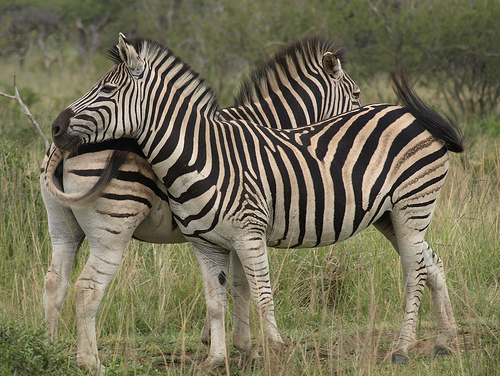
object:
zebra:
[33, 26, 376, 374]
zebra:
[51, 30, 470, 368]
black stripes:
[269, 127, 325, 249]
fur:
[51, 29, 454, 356]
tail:
[386, 67, 466, 154]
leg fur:
[61, 150, 150, 372]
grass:
[0, 0, 499, 376]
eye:
[100, 84, 117, 93]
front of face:
[49, 63, 138, 155]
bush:
[419, 42, 499, 122]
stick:
[0, 70, 52, 150]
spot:
[217, 269, 228, 286]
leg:
[55, 146, 156, 374]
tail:
[43, 144, 133, 210]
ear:
[117, 30, 145, 76]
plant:
[221, 0, 500, 85]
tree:
[1, 0, 126, 77]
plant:
[315, 251, 446, 375]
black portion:
[79, 143, 132, 204]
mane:
[103, 37, 219, 125]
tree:
[402, 1, 499, 122]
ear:
[321, 51, 341, 81]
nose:
[52, 118, 70, 137]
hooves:
[196, 348, 229, 371]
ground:
[0, 0, 499, 373]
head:
[50, 32, 146, 152]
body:
[176, 101, 449, 246]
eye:
[353, 91, 360, 99]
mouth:
[54, 135, 79, 152]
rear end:
[38, 139, 148, 246]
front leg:
[189, 237, 233, 370]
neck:
[137, 65, 211, 197]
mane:
[233, 31, 348, 109]